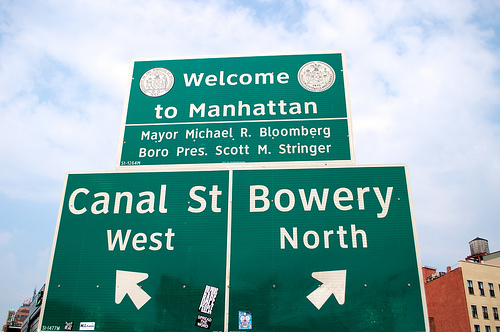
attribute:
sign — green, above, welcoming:
[118, 49, 360, 164]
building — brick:
[417, 233, 497, 330]